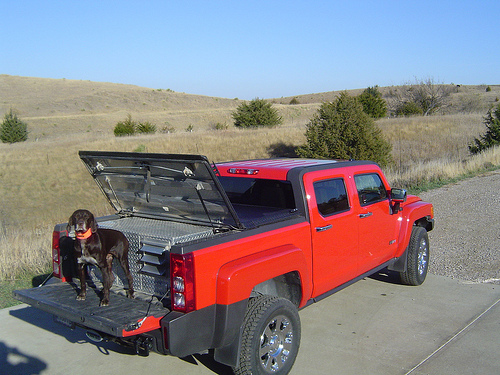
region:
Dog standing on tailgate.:
[56, 206, 140, 308]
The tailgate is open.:
[8, 272, 177, 349]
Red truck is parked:
[12, 142, 454, 373]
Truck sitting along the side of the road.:
[11, 122, 437, 374]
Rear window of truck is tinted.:
[196, 174, 303, 220]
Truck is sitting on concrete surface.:
[0, 222, 499, 374]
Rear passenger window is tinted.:
[310, 170, 353, 220]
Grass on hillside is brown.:
[3, 75, 496, 307]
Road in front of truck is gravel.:
[404, 166, 499, 288]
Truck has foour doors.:
[214, 154, 421, 298]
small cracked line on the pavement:
[439, 260, 494, 288]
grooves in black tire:
[242, 293, 279, 313]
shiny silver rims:
[263, 317, 302, 364]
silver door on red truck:
[314, 221, 336, 240]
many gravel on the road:
[453, 195, 490, 237]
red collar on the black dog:
[73, 219, 99, 242]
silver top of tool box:
[109, 206, 213, 251]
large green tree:
[300, 88, 401, 155]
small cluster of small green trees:
[112, 114, 210, 134]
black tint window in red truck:
[308, 170, 365, 226]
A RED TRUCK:
[9, 146, 444, 372]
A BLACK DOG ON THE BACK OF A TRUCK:
[34, 186, 219, 341]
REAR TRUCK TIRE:
[230, 292, 305, 374]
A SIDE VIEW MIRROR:
[376, 175, 416, 213]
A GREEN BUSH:
[295, 83, 402, 180]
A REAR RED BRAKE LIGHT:
[159, 248, 229, 319]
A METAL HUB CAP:
[253, 311, 299, 373]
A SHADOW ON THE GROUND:
[2, 326, 59, 373]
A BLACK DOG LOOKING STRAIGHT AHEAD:
[51, 207, 156, 313]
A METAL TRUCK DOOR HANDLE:
[313, 218, 338, 241]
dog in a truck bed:
[60, 210, 154, 321]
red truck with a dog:
[51, 105, 498, 336]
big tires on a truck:
[222, 280, 315, 369]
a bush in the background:
[225, 100, 347, 160]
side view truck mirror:
[368, 172, 422, 227]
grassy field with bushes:
[37, 90, 218, 157]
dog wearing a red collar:
[77, 219, 105, 248]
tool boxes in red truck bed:
[80, 207, 230, 344]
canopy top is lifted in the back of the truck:
[31, 125, 304, 336]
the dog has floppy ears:
[48, 194, 146, 298]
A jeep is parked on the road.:
[5, 137, 459, 372]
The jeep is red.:
[12, 129, 436, 373]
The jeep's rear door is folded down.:
[14, 274, 175, 349]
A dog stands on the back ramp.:
[48, 200, 143, 314]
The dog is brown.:
[47, 203, 141, 306]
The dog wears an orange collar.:
[68, 222, 97, 243]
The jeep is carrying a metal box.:
[82, 197, 217, 304]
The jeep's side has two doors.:
[292, 157, 399, 301]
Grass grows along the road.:
[368, 116, 494, 197]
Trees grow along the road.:
[273, 82, 398, 182]